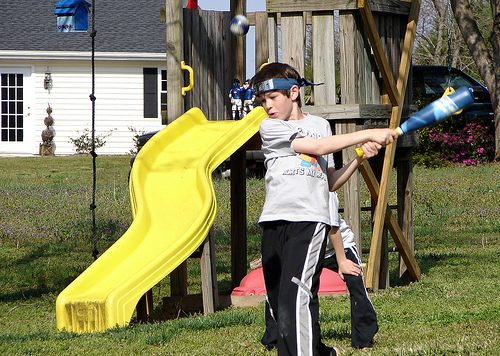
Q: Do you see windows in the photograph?
A: Yes, there are windows.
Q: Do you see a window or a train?
A: Yes, there are windows.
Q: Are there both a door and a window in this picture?
A: Yes, there are both a window and a door.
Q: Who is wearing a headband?
A: The boy is wearing a headband.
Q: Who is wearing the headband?
A: The boy is wearing a headband.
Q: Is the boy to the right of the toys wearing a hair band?
A: Yes, the boy is wearing a hair band.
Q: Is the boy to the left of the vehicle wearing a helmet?
A: No, the boy is wearing a hair band.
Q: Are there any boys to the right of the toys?
A: Yes, there is a boy to the right of the toys.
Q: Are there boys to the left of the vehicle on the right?
A: Yes, there is a boy to the left of the vehicle.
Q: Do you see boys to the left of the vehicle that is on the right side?
A: Yes, there is a boy to the left of the vehicle.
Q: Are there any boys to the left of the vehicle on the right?
A: Yes, there is a boy to the left of the vehicle.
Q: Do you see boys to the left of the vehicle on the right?
A: Yes, there is a boy to the left of the vehicle.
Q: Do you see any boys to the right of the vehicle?
A: No, the boy is to the left of the vehicle.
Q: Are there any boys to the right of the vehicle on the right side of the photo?
A: No, the boy is to the left of the vehicle.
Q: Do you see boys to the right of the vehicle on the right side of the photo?
A: No, the boy is to the left of the vehicle.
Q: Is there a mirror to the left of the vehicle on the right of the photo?
A: No, there is a boy to the left of the vehicle.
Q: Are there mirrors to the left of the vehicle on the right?
A: No, there is a boy to the left of the vehicle.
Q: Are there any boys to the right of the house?
A: Yes, there is a boy to the right of the house.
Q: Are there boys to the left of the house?
A: No, the boy is to the right of the house.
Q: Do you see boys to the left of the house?
A: No, the boy is to the right of the house.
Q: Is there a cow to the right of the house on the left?
A: No, there is a boy to the right of the house.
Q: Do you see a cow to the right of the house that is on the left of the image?
A: No, there is a boy to the right of the house.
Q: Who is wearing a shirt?
A: The boy is wearing a shirt.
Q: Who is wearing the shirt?
A: The boy is wearing a shirt.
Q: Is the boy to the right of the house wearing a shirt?
A: Yes, the boy is wearing a shirt.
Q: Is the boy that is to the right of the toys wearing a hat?
A: No, the boy is wearing a shirt.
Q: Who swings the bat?
A: The boy swings the bat.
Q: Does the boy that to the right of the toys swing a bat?
A: Yes, the boy swings a bat.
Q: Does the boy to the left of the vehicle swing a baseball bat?
A: No, the boy swings a bat.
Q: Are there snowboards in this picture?
A: No, there are no snowboards.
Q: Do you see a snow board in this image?
A: No, there are no snowboards.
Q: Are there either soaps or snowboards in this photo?
A: No, there are no snowboards or soaps.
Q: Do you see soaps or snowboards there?
A: No, there are no snowboards or soaps.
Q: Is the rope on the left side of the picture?
A: Yes, the rope is on the left of the image.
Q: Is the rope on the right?
A: No, the rope is on the left of the image.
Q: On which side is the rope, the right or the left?
A: The rope is on the left of the image.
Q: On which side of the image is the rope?
A: The rope is on the left of the image.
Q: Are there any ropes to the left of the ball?
A: Yes, there is a rope to the left of the ball.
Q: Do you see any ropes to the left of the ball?
A: Yes, there is a rope to the left of the ball.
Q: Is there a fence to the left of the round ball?
A: No, there is a rope to the left of the ball.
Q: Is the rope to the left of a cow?
A: No, the rope is to the left of the ball.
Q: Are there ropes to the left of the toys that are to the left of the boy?
A: Yes, there is a rope to the left of the toys.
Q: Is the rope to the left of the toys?
A: Yes, the rope is to the left of the toys.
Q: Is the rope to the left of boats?
A: No, the rope is to the left of the toys.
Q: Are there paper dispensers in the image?
A: No, there are no paper dispensers.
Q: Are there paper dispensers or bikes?
A: No, there are no paper dispensers or bikes.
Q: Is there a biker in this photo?
A: No, there are no bikers.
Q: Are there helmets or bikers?
A: No, there are no bikers or helmets.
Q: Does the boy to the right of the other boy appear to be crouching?
A: Yes, the boy is crouching.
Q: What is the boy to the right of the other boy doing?
A: The boy is crouching.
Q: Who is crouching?
A: The boy is crouching.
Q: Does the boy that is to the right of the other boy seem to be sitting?
A: No, the boy is crouching.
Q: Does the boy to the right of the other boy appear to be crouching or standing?
A: The boy is crouching.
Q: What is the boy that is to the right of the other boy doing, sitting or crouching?
A: The boy is crouching.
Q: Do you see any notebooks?
A: No, there are no notebooks.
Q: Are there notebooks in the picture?
A: No, there are no notebooks.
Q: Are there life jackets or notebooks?
A: No, there are no notebooks or life jackets.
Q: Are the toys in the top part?
A: Yes, the toys are in the top of the image.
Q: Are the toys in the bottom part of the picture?
A: No, the toys are in the top of the image.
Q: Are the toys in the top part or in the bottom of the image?
A: The toys are in the top of the image.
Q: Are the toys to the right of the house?
A: Yes, the toys are to the right of the house.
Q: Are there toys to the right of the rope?
A: Yes, there are toys to the right of the rope.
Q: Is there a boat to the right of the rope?
A: No, there are toys to the right of the rope.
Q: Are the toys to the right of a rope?
A: Yes, the toys are to the right of a rope.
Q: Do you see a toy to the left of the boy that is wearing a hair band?
A: Yes, there are toys to the left of the boy.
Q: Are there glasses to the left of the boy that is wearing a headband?
A: No, there are toys to the left of the boy.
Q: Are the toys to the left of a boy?
A: Yes, the toys are to the left of a boy.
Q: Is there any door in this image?
A: Yes, there is a door.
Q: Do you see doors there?
A: Yes, there is a door.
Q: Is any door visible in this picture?
A: Yes, there is a door.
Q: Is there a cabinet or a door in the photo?
A: Yes, there is a door.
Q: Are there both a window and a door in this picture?
A: Yes, there are both a door and a window.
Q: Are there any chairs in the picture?
A: No, there are no chairs.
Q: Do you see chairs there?
A: No, there are no chairs.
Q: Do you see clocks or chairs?
A: No, there are no chairs or clocks.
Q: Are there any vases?
A: No, there are no vases.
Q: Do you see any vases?
A: No, there are no vases.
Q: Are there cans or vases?
A: No, there are no vases or cans.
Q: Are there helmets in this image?
A: No, there are no helmets.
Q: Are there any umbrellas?
A: No, there are no umbrellas.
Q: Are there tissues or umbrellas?
A: No, there are no umbrellas or tissues.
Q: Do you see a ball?
A: Yes, there is a ball.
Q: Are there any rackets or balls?
A: Yes, there is a ball.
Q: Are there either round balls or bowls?
A: Yes, there is a round ball.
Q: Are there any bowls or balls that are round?
A: Yes, the ball is round.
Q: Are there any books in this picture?
A: No, there are no books.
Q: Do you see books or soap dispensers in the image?
A: No, there are no books or soap dispensers.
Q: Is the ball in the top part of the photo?
A: Yes, the ball is in the top of the image.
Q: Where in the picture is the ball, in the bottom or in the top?
A: The ball is in the top of the image.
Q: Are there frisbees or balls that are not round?
A: No, there is a ball but it is round.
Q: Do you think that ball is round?
A: Yes, the ball is round.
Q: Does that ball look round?
A: Yes, the ball is round.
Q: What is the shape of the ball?
A: The ball is round.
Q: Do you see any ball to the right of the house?
A: Yes, there is a ball to the right of the house.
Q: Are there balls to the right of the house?
A: Yes, there is a ball to the right of the house.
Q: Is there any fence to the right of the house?
A: No, there is a ball to the right of the house.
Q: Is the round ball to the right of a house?
A: Yes, the ball is to the right of a house.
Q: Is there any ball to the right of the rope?
A: Yes, there is a ball to the right of the rope.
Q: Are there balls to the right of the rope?
A: Yes, there is a ball to the right of the rope.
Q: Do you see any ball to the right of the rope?
A: Yes, there is a ball to the right of the rope.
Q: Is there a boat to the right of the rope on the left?
A: No, there is a ball to the right of the rope.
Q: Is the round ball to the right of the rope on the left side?
A: Yes, the ball is to the right of the rope.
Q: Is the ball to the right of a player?
A: No, the ball is to the right of the rope.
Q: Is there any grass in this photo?
A: Yes, there is grass.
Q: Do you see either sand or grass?
A: Yes, there is grass.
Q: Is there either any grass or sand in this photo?
A: Yes, there is grass.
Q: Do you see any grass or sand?
A: Yes, there is grass.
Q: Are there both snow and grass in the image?
A: No, there is grass but no snow.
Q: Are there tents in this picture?
A: No, there are no tents.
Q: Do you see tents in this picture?
A: No, there are no tents.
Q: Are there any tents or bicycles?
A: No, there are no tents or bicycles.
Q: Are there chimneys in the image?
A: No, there are no chimneys.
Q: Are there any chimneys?
A: No, there are no chimneys.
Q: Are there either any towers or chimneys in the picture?
A: No, there are no chimneys or towers.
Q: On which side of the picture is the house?
A: The house is on the left of the image.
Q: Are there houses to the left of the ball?
A: Yes, there is a house to the left of the ball.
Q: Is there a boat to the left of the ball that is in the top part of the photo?
A: No, there is a house to the left of the ball.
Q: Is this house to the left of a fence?
A: No, the house is to the left of the ball.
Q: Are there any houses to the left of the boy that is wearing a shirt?
A: Yes, there is a house to the left of the boy.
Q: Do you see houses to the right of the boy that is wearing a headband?
A: No, the house is to the left of the boy.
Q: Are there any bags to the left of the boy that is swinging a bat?
A: No, there is a house to the left of the boy.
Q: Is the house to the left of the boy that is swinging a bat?
A: Yes, the house is to the left of the boy.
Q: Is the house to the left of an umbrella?
A: No, the house is to the left of the boy.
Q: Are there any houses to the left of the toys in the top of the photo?
A: Yes, there is a house to the left of the toys.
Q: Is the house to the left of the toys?
A: Yes, the house is to the left of the toys.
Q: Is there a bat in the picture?
A: Yes, there is a bat.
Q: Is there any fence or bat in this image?
A: Yes, there is a bat.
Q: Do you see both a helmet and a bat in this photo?
A: No, there is a bat but no helmets.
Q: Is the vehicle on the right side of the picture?
A: Yes, the vehicle is on the right of the image.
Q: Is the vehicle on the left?
A: No, the vehicle is on the right of the image.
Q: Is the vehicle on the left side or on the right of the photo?
A: The vehicle is on the right of the image.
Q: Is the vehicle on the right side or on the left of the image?
A: The vehicle is on the right of the image.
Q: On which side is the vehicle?
A: The vehicle is on the right of the image.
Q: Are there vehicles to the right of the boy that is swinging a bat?
A: Yes, there is a vehicle to the right of the boy.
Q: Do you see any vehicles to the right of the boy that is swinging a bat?
A: Yes, there is a vehicle to the right of the boy.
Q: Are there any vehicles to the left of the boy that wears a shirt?
A: No, the vehicle is to the right of the boy.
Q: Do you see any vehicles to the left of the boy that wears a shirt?
A: No, the vehicle is to the right of the boy.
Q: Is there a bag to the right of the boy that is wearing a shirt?
A: No, there is a vehicle to the right of the boy.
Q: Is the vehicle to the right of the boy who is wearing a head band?
A: Yes, the vehicle is to the right of the boy.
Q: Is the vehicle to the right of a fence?
A: No, the vehicle is to the right of the boy.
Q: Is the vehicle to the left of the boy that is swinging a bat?
A: No, the vehicle is to the right of the boy.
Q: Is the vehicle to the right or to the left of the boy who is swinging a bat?
A: The vehicle is to the right of the boy.